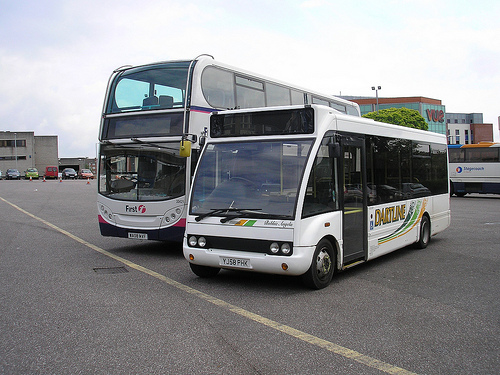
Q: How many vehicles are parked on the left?
A: 5.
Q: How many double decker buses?
A: 1.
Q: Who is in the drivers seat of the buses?
A: No one.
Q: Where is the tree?
A: Behind the buses.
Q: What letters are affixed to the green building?
A: VO2.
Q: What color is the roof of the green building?
A: Red.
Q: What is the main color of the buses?
A: White.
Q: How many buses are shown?
A: 3.